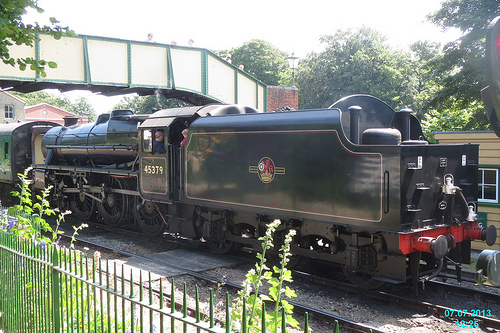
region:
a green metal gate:
[0, 232, 207, 330]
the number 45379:
[142, 164, 164, 177]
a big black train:
[18, 106, 471, 282]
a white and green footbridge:
[13, 32, 273, 101]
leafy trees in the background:
[253, 37, 482, 97]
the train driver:
[138, 124, 168, 155]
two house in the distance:
[0, 90, 85, 127]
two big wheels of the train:
[67, 177, 135, 227]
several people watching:
[141, 32, 253, 75]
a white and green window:
[480, 164, 498, 204]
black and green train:
[1, 97, 483, 293]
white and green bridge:
[1, 24, 269, 114]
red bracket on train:
[397, 217, 487, 261]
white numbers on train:
[143, 163, 165, 175]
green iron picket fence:
[1, 233, 345, 330]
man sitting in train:
[153, 129, 164, 151]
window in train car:
[143, 127, 165, 155]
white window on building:
[479, 166, 499, 201]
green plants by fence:
[11, 168, 102, 328]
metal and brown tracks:
[408, 275, 498, 328]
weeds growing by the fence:
[221, 213, 301, 327]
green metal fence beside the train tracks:
[22, 255, 129, 331]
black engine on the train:
[134, 85, 490, 277]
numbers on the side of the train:
[136, 160, 166, 179]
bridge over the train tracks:
[30, 11, 315, 116]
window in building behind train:
[466, 155, 498, 209]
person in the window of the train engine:
[149, 123, 165, 157]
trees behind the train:
[294, 31, 431, 118]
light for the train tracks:
[484, 11, 498, 145]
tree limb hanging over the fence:
[3, 0, 64, 94]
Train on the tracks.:
[0, 113, 482, 291]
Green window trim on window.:
[477, 160, 498, 206]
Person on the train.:
[147, 128, 163, 157]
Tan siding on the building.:
[434, 130, 499, 252]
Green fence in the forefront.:
[1, 226, 346, 331]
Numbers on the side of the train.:
[141, 163, 165, 177]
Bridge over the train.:
[0, 20, 271, 110]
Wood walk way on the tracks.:
[90, 243, 232, 293]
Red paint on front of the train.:
[400, 217, 487, 258]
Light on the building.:
[285, 50, 300, 91]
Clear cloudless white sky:
[191, 2, 316, 37]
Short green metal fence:
[76, 260, 152, 326]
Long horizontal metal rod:
[63, 268, 104, 294]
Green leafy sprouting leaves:
[17, 186, 54, 236]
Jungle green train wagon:
[194, 129, 359, 196]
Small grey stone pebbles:
[303, 279, 331, 307]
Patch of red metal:
[399, 235, 428, 250]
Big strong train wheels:
[75, 188, 135, 223]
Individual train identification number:
[141, 162, 168, 183]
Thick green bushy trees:
[306, 56, 378, 86]